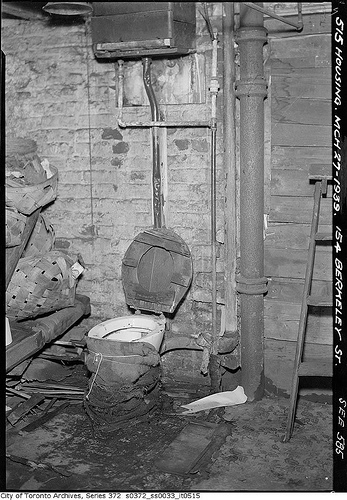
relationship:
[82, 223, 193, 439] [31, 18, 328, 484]
toilet in room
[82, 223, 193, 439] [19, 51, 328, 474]
toilet in room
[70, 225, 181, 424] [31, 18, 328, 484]
toilet in room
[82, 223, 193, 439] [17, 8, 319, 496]
toilet in room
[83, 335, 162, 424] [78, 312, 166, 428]
bag wrapped around toilet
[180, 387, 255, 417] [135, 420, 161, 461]
paper on floor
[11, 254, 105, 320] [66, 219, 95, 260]
basket against wall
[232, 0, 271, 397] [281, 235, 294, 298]
drain pipe along wall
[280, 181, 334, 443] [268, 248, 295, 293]
ladder against wall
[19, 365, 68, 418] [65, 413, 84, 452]
wood on floor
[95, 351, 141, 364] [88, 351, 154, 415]
cord around bag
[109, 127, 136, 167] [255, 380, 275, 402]
stains on wall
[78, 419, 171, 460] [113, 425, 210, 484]
dirt on floor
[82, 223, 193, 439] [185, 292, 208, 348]
toilet against wall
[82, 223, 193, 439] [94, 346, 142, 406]
toilet wrapped in cloth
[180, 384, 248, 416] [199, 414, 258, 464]
paper on ground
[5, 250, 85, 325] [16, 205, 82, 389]
basket of trash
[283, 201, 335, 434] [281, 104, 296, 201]
ladder leaning against wall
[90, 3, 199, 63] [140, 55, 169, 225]
box leading to pipe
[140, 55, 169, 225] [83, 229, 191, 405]
pipe connected to toilet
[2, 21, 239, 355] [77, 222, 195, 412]
wall behind toilet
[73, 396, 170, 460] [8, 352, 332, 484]
dirt on ground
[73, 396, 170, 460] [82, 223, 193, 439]
dirt in front of toilet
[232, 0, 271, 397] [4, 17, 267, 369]
drain pipe on wall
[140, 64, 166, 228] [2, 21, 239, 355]
pipe on wall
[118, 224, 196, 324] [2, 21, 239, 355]
toilet seat against wall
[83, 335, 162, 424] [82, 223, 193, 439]
bag in front of a toilet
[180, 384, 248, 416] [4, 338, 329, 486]
paper on floor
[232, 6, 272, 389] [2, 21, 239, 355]
drain pipe running up wall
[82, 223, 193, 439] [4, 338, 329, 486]
toilet on floor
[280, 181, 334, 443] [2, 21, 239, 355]
ladder leaning against wall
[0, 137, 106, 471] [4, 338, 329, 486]
debris pile on floor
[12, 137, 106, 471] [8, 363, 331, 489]
debris pile on floor